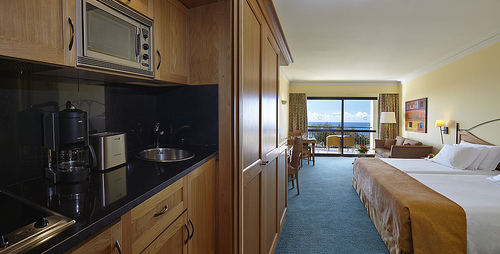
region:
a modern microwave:
[79, 0, 156, 72]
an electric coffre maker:
[52, 102, 95, 182]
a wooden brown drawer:
[130, 193, 184, 245]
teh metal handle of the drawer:
[153, 203, 166, 215]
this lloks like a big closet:
[244, 28, 288, 244]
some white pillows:
[434, 140, 499, 170]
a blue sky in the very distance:
[305, 95, 370, 126]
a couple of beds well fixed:
[361, 150, 498, 251]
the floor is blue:
[299, 175, 359, 251]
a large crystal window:
[310, 98, 378, 153]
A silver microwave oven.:
[71, 0, 154, 72]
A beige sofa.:
[371, 133, 433, 155]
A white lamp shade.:
[380, 110, 396, 126]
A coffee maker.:
[45, 100, 97, 192]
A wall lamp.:
[435, 116, 447, 146]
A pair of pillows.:
[434, 136, 499, 174]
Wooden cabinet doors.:
[238, 3, 285, 252]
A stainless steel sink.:
[138, 143, 193, 165]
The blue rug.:
[308, 161, 350, 248]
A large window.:
[306, 93, 377, 154]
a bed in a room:
[361, 65, 491, 217]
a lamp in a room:
[375, 113, 416, 148]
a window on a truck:
[311, 62, 423, 167]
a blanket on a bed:
[343, 131, 465, 224]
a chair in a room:
[288, 97, 349, 184]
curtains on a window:
[360, 85, 415, 147]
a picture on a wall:
[397, 88, 448, 134]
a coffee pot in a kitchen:
[46, 73, 141, 195]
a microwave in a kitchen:
[72, 9, 209, 84]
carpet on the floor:
[317, 135, 368, 227]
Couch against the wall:
[369, 129, 430, 161]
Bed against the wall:
[352, 126, 497, 252]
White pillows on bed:
[428, 134, 498, 178]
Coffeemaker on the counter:
[32, 94, 94, 184]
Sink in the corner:
[125, 109, 200, 176]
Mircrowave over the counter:
[70, 1, 164, 81]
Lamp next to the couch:
[377, 104, 404, 148]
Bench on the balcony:
[320, 121, 357, 154]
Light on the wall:
[429, 107, 454, 142]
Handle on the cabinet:
[60, 13, 80, 56]